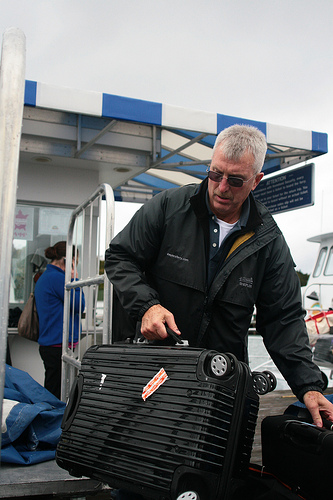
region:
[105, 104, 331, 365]
a man with grey hair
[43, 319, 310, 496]
a suitcase made of plastic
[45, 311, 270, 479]
the suitcase is black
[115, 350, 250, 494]
a red and white sticker on a suitcase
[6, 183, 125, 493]
a metal cart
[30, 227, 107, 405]
a woman in a blue jacket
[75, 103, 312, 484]
a man loading luggage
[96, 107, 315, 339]
a man in a black jacket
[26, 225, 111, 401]
a woman talks on a cellphone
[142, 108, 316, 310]
a man wearing sunglasses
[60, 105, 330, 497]
Man holding a suitcase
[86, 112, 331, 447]
Man has grey hair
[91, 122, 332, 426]
Man has black glasses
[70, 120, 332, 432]
Man wears a jacket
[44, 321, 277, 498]
Plastic suitcase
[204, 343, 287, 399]
Wheels of suitcase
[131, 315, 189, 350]
Handle of suitcase is black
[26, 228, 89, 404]
Woman talking by phone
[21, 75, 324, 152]
Roof is white and blue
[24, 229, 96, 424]
Woman wears a blue jacket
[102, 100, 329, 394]
man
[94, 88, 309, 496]
a man caring luggage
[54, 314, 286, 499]
the suitcase is black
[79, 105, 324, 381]
the man is wearing sunglasses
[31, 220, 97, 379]
a woman talks on a phone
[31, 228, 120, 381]
the woman is wearing a blue coat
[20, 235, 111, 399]
the woman is carrying a pocketbook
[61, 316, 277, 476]
the luggage has wheels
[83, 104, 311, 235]
the man has grey hair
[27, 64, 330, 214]
the building has a blue and white roof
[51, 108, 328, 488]
The man is picking up a suitcase.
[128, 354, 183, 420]
A sticker is on the suitcase.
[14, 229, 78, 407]
The woman is talking on a cellphone.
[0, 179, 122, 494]
A cart.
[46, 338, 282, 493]
The suitcase is made from plastic.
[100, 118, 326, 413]
The man is wearing a black jacket.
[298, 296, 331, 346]
A red and brown bag in the background.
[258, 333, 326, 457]
The man has his left hand on another bag.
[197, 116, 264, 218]
The man has sunglasses on.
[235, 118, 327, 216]
A blue and white sign is attached to the roof.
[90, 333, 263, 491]
A black Suit Case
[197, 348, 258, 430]
A wheel on a black Suit Case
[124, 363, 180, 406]
A tag on a black Suit Case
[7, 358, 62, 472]
A blue tarp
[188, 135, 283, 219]
A man wearing glasses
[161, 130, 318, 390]
A man wearing a black coat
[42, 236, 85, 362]
A woman in a blue coat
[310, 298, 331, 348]
A red and white bag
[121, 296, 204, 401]
A hand holding a suitcase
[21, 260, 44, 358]
A woman's purse